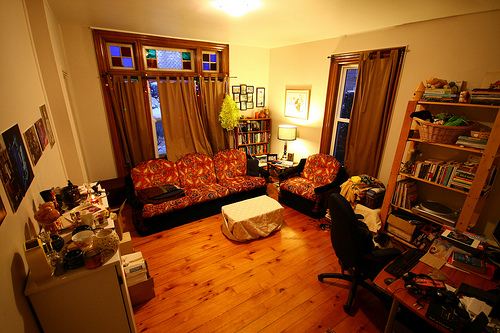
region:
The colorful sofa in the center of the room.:
[129, 155, 264, 210]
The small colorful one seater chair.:
[273, 140, 340, 212]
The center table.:
[208, 195, 297, 240]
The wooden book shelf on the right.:
[383, 76, 495, 239]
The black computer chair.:
[320, 192, 397, 292]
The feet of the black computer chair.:
[311, 266, 374, 324]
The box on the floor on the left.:
[118, 250, 151, 305]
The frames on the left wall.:
[3, 105, 53, 187]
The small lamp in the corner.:
[272, 115, 292, 160]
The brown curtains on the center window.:
[110, 75, 250, 167]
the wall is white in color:
[276, 20, 310, 65]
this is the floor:
[186, 257, 320, 312]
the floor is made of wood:
[211, 260, 296, 315]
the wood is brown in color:
[201, 263, 293, 315]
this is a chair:
[111, 150, 351, 212]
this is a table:
[216, 195, 290, 242]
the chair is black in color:
[331, 213, 348, 250]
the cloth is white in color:
[247, 208, 262, 233]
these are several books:
[420, 159, 470, 187]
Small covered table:
[218, 190, 289, 248]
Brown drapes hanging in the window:
[154, 74, 245, 157]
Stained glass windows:
[99, 25, 229, 75]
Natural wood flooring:
[171, 251, 309, 331]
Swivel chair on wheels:
[315, 186, 407, 323]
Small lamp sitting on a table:
[275, 119, 297, 164]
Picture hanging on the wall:
[280, 80, 312, 121]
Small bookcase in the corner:
[232, 111, 273, 167]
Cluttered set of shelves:
[378, 76, 498, 240]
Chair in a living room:
[275, 148, 342, 217]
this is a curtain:
[168, 79, 215, 149]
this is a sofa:
[187, 148, 245, 197]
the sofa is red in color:
[190, 146, 241, 194]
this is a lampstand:
[274, 122, 301, 142]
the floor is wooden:
[191, 252, 304, 331]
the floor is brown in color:
[197, 247, 306, 331]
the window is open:
[153, 110, 167, 138]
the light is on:
[225, 1, 255, 20]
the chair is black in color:
[323, 199, 371, 272]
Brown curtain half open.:
[326, 46, 410, 179]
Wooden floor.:
[160, 240, 313, 328]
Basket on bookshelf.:
[403, 98, 473, 153]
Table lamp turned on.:
[271, 120, 296, 161]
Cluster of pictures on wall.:
[230, 80, 265, 110]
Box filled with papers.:
[120, 246, 155, 308]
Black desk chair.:
[315, 190, 391, 316]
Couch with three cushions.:
[121, 150, 257, 225]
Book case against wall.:
[226, 111, 271, 156]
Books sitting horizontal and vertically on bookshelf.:
[396, 136, 493, 201]